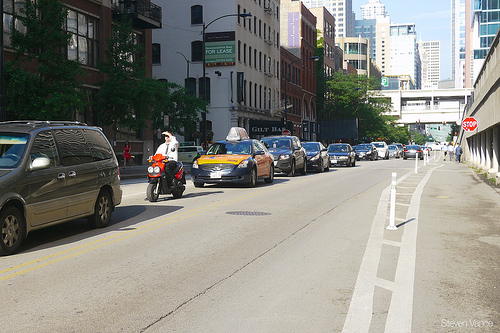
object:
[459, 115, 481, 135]
sign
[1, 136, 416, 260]
street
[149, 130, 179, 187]
man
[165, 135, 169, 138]
eyes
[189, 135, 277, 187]
car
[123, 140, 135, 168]
woman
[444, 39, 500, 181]
building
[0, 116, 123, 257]
minivan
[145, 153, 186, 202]
scooter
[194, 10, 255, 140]
streetlight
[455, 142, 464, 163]
people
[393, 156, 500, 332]
sidewalk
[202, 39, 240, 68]
sign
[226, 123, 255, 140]
sign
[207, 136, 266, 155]
cartop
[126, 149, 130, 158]
red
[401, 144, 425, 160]
vehicles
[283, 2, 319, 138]
building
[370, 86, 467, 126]
walkway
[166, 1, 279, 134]
building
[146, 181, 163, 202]
tire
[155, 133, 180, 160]
shirt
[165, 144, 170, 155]
tie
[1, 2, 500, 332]
city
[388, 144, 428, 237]
dividers